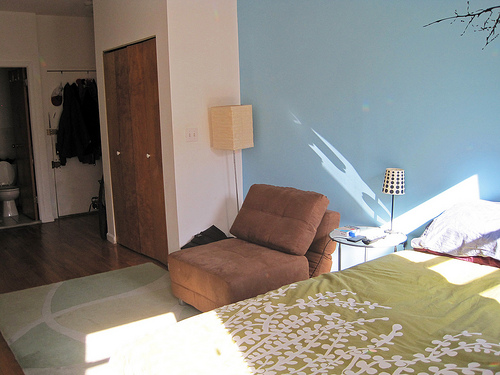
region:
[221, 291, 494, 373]
white flower pattern on the bed spread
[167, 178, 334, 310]
a brown chair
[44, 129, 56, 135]
a door lock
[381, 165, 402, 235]
lamp on the night stand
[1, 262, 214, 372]
green area rug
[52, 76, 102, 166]
jackets hanging on the back of the door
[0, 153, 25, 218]
the toilet is white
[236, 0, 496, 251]
a blue accent wall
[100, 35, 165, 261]
the closet doors are wood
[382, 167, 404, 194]
black pok a dots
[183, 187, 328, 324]
the chair is brown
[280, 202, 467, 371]
the bed is made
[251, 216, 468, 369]
the bed is made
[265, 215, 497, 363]
the bed is made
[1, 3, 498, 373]
this looks like a hotel room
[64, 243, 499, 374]
the bedspread is green and white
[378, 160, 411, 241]
a little reading lamp beside the bed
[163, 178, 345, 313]
this might be a fold-out futon thing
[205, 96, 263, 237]
floor lamp in the corner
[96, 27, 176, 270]
the closet has two accordion style doors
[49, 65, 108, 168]
clothes hanging up in the background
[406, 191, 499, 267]
rumpled pillow at the head of the bed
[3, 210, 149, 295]
parquet floor looks very nice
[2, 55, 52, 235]
the bathroom looks pretty small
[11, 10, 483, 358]
A large bedroom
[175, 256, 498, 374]
A green bedspread with white print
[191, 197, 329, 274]
A brown chair next to bed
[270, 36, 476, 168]
A light blue wall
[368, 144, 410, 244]
A small lamp with black and white shade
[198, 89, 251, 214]
A lamp with beige shade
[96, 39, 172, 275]
Brown doors with white knobs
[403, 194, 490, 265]
Pillow on top of bed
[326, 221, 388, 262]
A round table beside bed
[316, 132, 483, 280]
Sunlight shining on bed and wall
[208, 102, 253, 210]
lamp with a square shade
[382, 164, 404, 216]
white lamp shade with black dots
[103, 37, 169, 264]
wood closet doors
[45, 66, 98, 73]
mtal bar in the closet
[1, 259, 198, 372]
green and yellow area rug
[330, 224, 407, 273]
round night stand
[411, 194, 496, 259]
pillow on the bed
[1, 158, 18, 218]
white toilet with open lid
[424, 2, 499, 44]
part of a black tree branch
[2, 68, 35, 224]
open bathroom doorway